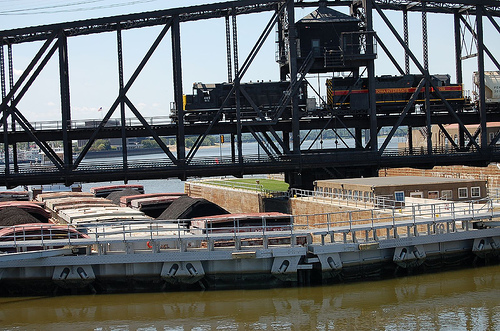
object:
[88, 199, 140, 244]
car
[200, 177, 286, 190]
grass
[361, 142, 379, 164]
ground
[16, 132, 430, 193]
water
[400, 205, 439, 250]
ground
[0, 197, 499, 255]
railing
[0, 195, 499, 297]
dock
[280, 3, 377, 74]
house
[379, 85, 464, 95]
orange stripe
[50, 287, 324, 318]
reflections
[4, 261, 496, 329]
water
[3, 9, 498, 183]
sky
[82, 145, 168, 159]
ship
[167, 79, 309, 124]
engine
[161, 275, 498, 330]
water surface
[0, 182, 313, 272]
cargo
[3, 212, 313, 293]
gate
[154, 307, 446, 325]
reflection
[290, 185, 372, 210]
rails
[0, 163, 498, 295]
ferry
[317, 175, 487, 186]
roof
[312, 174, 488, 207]
building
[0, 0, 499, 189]
bridge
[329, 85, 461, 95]
stripe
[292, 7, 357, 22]
roof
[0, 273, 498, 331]
river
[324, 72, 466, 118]
engines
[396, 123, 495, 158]
building